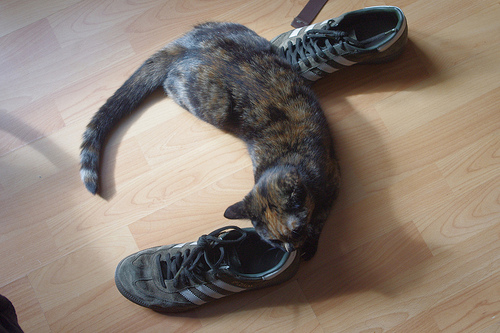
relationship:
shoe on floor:
[94, 231, 321, 308] [0, 230, 497, 330]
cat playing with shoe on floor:
[80, 19, 341, 254] [1, 1, 497, 330]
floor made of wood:
[346, 95, 483, 315] [83, 212, 153, 333]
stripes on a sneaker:
[180, 273, 233, 333] [99, 222, 327, 329]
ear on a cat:
[223, 200, 253, 222] [80, 19, 341, 254]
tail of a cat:
[74, 116, 133, 241] [80, 19, 341, 254]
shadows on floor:
[327, 99, 437, 302] [325, 67, 477, 333]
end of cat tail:
[68, 157, 102, 242] [77, 112, 117, 213]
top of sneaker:
[115, 214, 294, 309] [116, 222, 291, 314]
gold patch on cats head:
[260, 205, 282, 236] [224, 173, 314, 273]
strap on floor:
[283, 0, 360, 25] [348, 109, 498, 209]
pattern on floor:
[1, 243, 90, 316] [1, 1, 497, 330]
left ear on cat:
[273, 175, 314, 204] [212, 192, 258, 278]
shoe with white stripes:
[270, 5, 407, 80] [179, 280, 245, 304]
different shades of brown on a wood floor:
[14, 179, 124, 326] [9, 30, 490, 330]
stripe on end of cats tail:
[83, 178, 99, 193] [79, 41, 181, 198]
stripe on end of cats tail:
[77, 168, 100, 180] [79, 41, 181, 198]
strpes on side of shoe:
[174, 270, 232, 333] [296, 23, 391, 58]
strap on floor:
[285, 6, 318, 26] [371, 69, 473, 176]